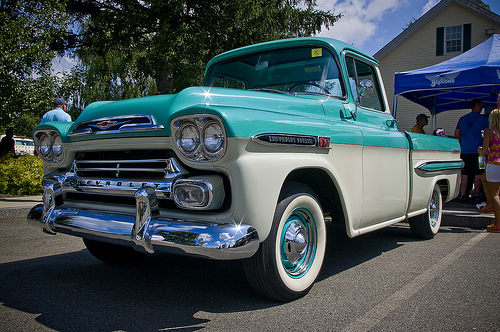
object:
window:
[203, 44, 339, 99]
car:
[27, 37, 462, 299]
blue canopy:
[391, 33, 500, 165]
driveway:
[3, 189, 497, 330]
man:
[41, 99, 72, 123]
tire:
[254, 194, 329, 301]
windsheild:
[205, 50, 342, 95]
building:
[371, 2, 499, 149]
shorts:
[482, 159, 499, 184]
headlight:
[175, 116, 225, 158]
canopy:
[389, 34, 500, 115]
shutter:
[436, 27, 444, 56]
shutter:
[462, 24, 471, 52]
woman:
[476, 106, 498, 231]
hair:
[488, 108, 499, 130]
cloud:
[325, 5, 357, 35]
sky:
[321, 1, 399, 55]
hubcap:
[280, 205, 318, 278]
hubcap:
[429, 192, 439, 225]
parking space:
[3, 211, 498, 330]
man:
[411, 113, 430, 135]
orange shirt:
[411, 123, 425, 133]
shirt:
[455, 112, 487, 154]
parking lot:
[3, 235, 498, 327]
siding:
[368, 1, 492, 137]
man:
[451, 95, 486, 207]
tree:
[64, 1, 344, 93]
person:
[3, 128, 16, 169]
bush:
[4, 159, 43, 199]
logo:
[87, 119, 131, 130]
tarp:
[425, 73, 460, 88]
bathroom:
[443, 26, 464, 54]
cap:
[54, 98, 68, 106]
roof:
[394, 32, 500, 110]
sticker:
[311, 48, 322, 58]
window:
[444, 25, 463, 51]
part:
[262, 249, 276, 269]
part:
[273, 222, 287, 256]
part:
[313, 244, 323, 258]